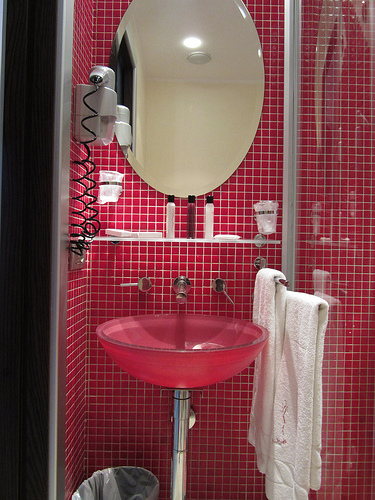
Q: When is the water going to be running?
A: When hands need to be washed.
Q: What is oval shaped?
A: A mirror.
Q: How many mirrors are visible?
A: One.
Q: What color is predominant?
A: Hot pink.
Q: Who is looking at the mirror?
A: The photographer.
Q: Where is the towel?
A: On a rack, by the sink.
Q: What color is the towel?
A: White.